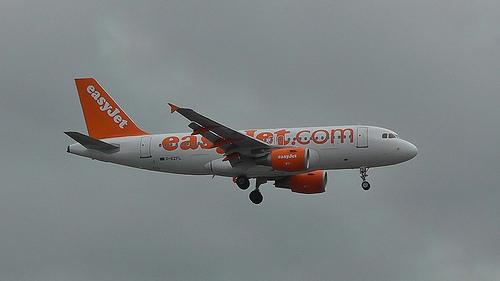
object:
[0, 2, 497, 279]
sky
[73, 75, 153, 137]
vertical stabilizer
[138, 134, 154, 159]
door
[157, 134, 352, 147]
windows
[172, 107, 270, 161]
wing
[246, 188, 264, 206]
wheel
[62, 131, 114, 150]
horizontal stabilizer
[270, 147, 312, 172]
turbine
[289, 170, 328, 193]
turbine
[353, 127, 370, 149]
door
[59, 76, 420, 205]
plane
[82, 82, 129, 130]
easyjet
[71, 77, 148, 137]
tail